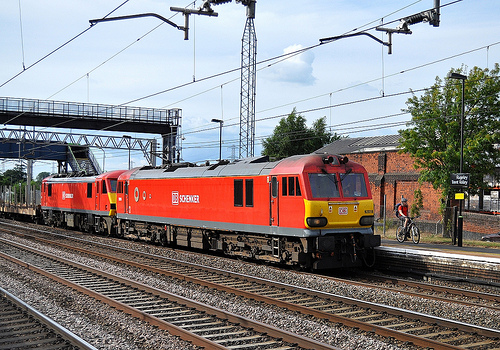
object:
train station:
[97, 101, 500, 268]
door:
[269, 175, 280, 226]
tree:
[28, 172, 51, 192]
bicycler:
[394, 198, 412, 241]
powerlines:
[0, 92, 500, 159]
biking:
[394, 215, 422, 245]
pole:
[218, 121, 222, 160]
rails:
[0, 213, 499, 348]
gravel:
[52, 293, 209, 350]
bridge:
[0, 96, 183, 164]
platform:
[382, 236, 496, 273]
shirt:
[397, 205, 408, 216]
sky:
[0, 0, 499, 173]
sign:
[449, 172, 470, 187]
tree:
[259, 106, 351, 161]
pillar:
[237, 20, 258, 159]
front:
[304, 200, 376, 229]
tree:
[393, 61, 500, 245]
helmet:
[401, 198, 408, 202]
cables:
[2, 0, 499, 162]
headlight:
[306, 216, 327, 227]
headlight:
[359, 215, 374, 226]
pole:
[458, 76, 465, 246]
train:
[30, 151, 381, 273]